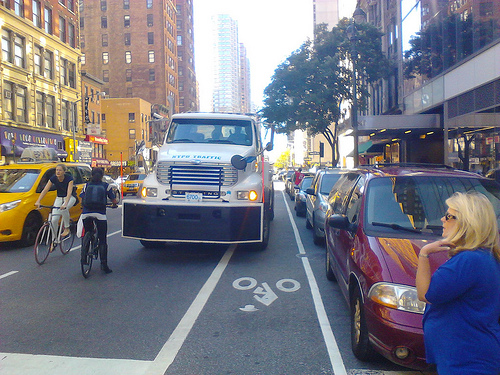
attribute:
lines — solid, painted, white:
[157, 245, 341, 372]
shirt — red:
[291, 170, 302, 187]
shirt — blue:
[415, 257, 492, 368]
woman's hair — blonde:
[443, 177, 494, 259]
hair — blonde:
[440, 185, 495, 254]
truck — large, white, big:
[121, 111, 274, 248]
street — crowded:
[8, 7, 499, 367]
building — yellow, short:
[97, 92, 173, 154]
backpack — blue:
[80, 180, 108, 210]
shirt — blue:
[406, 240, 499, 372]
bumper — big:
[119, 197, 267, 248]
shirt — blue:
[418, 248, 498, 372]